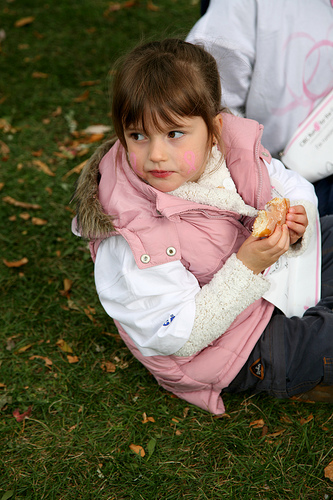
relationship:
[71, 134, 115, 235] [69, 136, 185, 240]
fur on hood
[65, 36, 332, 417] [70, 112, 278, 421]
girl wearing vest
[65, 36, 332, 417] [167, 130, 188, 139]
girl has eye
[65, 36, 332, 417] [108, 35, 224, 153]
girl has hair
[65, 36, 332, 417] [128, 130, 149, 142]
girl has eye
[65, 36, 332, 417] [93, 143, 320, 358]
girl wearing shirt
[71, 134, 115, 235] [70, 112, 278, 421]
fur on vest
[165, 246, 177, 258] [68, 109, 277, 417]
button on jacket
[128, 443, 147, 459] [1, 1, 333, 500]
leaf on ground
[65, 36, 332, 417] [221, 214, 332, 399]
girl wearing pants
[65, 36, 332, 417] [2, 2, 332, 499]
girl on grass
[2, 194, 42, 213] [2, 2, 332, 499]
leaf on grass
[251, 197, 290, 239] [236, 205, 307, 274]
donut in hands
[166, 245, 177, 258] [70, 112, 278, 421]
metal stud on vest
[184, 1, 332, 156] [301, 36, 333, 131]
shirt has symbol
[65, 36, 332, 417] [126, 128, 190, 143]
girl has eyes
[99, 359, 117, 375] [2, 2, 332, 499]
leaf on grass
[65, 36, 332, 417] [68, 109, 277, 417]
girl wearing jacket